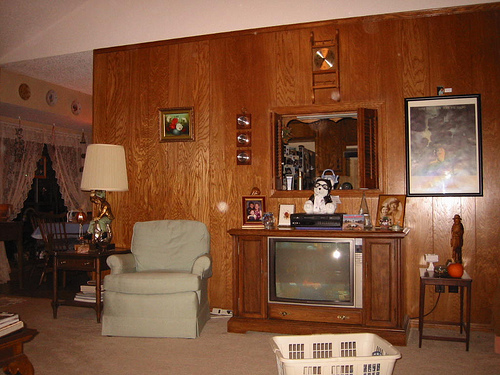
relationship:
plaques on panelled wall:
[236, 113, 251, 165] [91, 0, 500, 330]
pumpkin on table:
[449, 263, 464, 278] [420, 270, 472, 352]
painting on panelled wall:
[157, 106, 196, 143] [91, 0, 500, 330]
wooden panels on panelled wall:
[188, 49, 280, 98] [91, 0, 500, 330]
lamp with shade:
[88, 191, 116, 246] [78, 141, 130, 194]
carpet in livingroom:
[2, 292, 499, 374] [2, 1, 499, 373]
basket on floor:
[269, 330, 402, 374] [1, 292, 498, 373]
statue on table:
[447, 212, 468, 267] [415, 271, 472, 353]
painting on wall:
[157, 105, 195, 143] [91, 46, 222, 318]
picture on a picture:
[404, 95, 487, 198] [156, 100, 198, 142]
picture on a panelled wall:
[404, 95, 487, 198] [93, 0, 498, 329]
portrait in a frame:
[242, 199, 262, 224] [238, 195, 267, 226]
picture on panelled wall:
[404, 84, 485, 198] [91, 0, 500, 330]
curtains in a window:
[6, 127, 101, 250] [8, 154, 88, 287]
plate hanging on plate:
[15, 78, 35, 105] [43, 83, 58, 107]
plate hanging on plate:
[15, 78, 35, 105] [64, 94, 86, 115]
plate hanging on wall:
[15, 78, 35, 105] [6, 112, 73, 133]